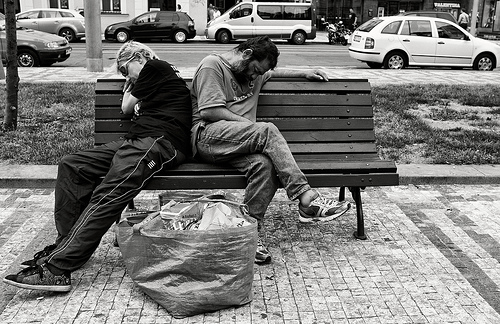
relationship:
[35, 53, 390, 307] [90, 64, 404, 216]
men sitting on a bench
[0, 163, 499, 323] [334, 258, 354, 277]
ground made of brick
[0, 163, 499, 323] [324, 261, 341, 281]
ground made of brick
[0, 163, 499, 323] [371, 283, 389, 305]
ground made of brick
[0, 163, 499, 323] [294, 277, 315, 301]
ground made of brick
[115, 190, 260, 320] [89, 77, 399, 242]
bag in front of bench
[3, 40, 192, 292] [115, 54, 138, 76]
men wearing wearing glasses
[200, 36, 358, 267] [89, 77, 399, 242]
man sleeping on bench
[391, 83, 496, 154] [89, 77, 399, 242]
grass behind bench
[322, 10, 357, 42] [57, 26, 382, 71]
motorcycle parked on road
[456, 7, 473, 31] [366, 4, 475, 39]
person walking in front of store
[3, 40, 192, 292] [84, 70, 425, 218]
men on a bench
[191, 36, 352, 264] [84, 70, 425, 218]
man on a bench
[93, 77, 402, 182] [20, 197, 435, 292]
bench on sidewalk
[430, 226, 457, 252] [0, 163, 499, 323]
brick on ground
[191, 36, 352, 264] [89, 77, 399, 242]
man sleeping on a bench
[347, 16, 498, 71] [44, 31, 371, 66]
car on road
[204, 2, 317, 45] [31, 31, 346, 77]
car on street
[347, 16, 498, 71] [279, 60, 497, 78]
car parked beside curb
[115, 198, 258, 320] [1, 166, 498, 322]
bag sitting on ground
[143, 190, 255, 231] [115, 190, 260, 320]
stuff inside bag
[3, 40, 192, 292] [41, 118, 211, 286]
men wearing pants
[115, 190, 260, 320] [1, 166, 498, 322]
bag on ground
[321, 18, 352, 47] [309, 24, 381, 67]
motorcycle in street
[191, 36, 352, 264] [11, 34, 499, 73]
man in street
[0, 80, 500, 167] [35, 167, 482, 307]
grass by sidewalk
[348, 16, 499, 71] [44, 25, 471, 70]
car on road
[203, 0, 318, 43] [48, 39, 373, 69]
car on road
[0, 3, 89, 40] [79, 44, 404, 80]
car on road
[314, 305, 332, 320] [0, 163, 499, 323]
brick on ground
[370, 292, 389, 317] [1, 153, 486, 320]
brick on sidewalk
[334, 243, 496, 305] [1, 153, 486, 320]
brick on sidewalk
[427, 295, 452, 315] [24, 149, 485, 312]
brick on sidewalk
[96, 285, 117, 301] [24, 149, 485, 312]
brick on sidewalk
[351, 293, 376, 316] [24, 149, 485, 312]
brick on sidewalk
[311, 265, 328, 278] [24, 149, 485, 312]
brick on sidewalk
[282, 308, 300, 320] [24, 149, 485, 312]
brick on sidewalk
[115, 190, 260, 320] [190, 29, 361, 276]
bag next to man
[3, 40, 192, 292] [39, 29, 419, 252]
men on bench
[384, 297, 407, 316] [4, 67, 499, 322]
brick on ground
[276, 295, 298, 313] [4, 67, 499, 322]
brick on ground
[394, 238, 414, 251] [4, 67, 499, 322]
brick on ground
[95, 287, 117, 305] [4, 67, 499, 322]
brick on ground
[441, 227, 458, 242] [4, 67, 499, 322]
brick on ground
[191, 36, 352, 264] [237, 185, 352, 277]
man wearing shoes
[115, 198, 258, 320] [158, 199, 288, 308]
bag in bag